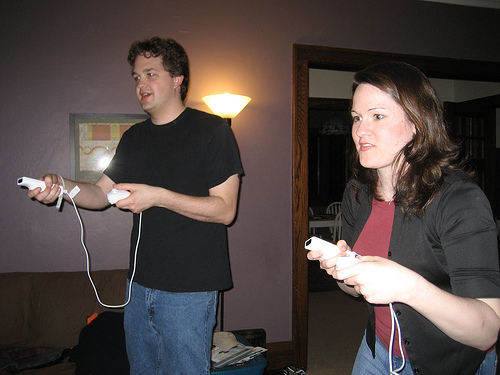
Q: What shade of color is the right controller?
A: White.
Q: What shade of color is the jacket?
A: Black.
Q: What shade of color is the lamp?
A: Yellow.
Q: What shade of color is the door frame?
A: Brown.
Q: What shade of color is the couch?
A: Brown.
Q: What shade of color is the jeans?
A: Blue.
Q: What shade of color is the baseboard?
A: Brown.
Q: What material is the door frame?
A: Wood.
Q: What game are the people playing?
A: Wii.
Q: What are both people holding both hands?
A: Wii remote.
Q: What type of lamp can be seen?
A: Floor lamp.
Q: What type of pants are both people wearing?
A: Jeans.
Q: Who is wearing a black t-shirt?
A: The man.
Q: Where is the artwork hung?
A: On wall above couch.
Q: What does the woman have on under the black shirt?
A: A red t-shirt.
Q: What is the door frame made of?
A: Brown wood.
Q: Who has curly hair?
A: The man.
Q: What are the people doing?
A: Playing a video game.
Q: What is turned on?
A: A light.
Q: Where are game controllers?
A: In people's hands.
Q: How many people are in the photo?
A: Two.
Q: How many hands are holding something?
A: Four.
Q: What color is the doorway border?
A: Brown.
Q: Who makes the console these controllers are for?
A: Nintendo.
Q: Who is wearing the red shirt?
A: Woman.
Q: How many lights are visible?
A: One.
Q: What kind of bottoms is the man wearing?
A: Jeans.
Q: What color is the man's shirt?
A: Black.